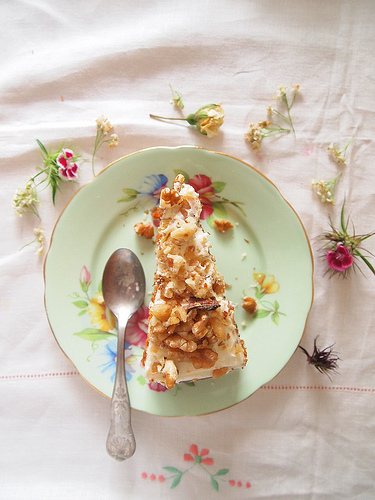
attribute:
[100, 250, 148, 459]
spoon — silver, shiny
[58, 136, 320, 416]
dish — green, white, gold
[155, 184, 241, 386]
pastry — brown, full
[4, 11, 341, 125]
tablecloth — white, plain, whie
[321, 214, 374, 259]
flower — purple, yellow, red, pink